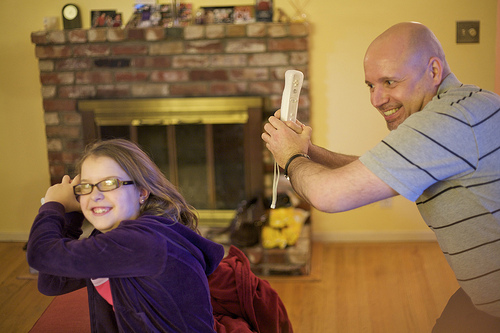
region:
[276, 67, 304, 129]
a white game controller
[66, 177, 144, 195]
a pair of dark eyeglasses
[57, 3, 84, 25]
a small black clock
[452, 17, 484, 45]
a gold light switch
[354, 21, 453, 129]
the head of a man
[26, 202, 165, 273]
the arm of a girl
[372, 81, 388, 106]
the nose of a man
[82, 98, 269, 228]
a gold fireplace cover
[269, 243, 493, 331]
light brown hardwood floor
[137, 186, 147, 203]
the ear of a girl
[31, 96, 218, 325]
little girl is playing a video game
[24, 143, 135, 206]
the girl is wearing glasses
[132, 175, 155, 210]
the girl is wearing earrings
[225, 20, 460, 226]
the man is holding a wii remote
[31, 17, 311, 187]
the mantel is made of bricks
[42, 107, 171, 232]
the girl is smiling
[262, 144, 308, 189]
the man is wearing a watch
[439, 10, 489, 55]
the light switch is on the wall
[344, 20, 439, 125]
the man is smiling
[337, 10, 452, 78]
the man is bald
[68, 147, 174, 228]
girl is wearing glasses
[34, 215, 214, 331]
the jacket is purple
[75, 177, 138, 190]
the glasses are brown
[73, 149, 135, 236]
the girl is smiling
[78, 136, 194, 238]
the girl has brown hair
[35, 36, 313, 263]
the fireplace is brick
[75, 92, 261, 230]
the fireplace is gold trim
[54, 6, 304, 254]
the clock is on fireplace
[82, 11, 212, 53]
photos on the fireplace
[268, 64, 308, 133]
game control is white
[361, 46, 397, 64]
head of a man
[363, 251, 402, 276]
part of a floor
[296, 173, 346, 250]
part of an elbow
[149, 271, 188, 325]
part of a jumper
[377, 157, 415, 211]
edge of a sleeve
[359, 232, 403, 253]
edge of a corner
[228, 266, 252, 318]
part of a jumper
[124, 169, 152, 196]
part of an ea r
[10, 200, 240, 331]
Purple jacket on a girl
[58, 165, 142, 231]
Glasses on a girl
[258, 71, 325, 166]
White Wii remote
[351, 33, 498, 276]
Stripped shirt on a man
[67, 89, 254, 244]
Brass fireplace cover on a fireplace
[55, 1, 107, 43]
Clock on a mantle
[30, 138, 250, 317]
Girl with a smile on her face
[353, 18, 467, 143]
Man with a bald head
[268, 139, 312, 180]
Watch on a man's wrist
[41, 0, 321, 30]
Pictures on a mantle